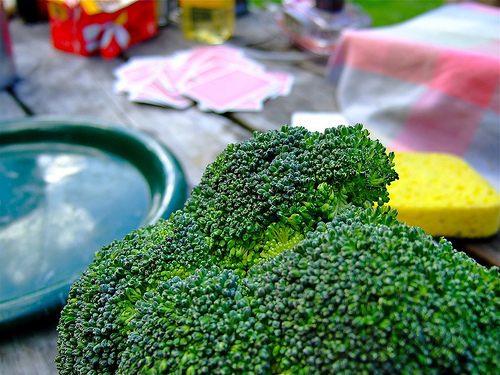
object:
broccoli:
[58, 121, 499, 374]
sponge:
[379, 145, 498, 245]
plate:
[1, 114, 190, 330]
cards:
[181, 66, 283, 114]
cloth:
[328, 0, 500, 190]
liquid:
[180, 1, 241, 46]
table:
[3, 3, 498, 375]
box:
[44, 1, 161, 63]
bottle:
[282, 1, 371, 54]